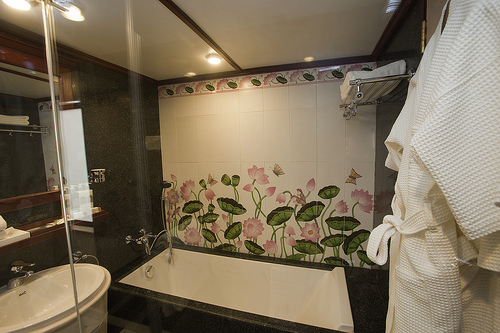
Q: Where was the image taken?
A: It was taken at the bathroom.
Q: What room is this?
A: It is a bathroom.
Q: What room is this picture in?
A: It is at the bathroom.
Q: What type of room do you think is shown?
A: It is a bathroom.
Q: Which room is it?
A: It is a bathroom.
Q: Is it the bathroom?
A: Yes, it is the bathroom.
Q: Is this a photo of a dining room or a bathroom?
A: It is showing a bathroom.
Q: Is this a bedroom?
A: No, it is a bathroom.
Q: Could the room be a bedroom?
A: No, it is a bathroom.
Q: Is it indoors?
A: Yes, it is indoors.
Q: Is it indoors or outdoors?
A: It is indoors.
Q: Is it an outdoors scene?
A: No, it is indoors.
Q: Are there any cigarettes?
A: No, there are no cigarettes.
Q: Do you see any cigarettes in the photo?
A: No, there are no cigarettes.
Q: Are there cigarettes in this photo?
A: No, there are no cigarettes.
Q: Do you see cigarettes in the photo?
A: No, there are no cigarettes.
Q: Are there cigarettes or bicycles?
A: No, there are no cigarettes or bicycles.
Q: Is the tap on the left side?
A: Yes, the tap is on the left of the image.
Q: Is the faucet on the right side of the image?
A: No, the faucet is on the left of the image.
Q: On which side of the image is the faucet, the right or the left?
A: The faucet is on the left of the image.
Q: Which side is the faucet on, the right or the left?
A: The faucet is on the left of the image.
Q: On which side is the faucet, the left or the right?
A: The faucet is on the left of the image.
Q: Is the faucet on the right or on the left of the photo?
A: The faucet is on the left of the image.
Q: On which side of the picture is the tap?
A: The tap is on the left of the image.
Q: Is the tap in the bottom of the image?
A: Yes, the tap is in the bottom of the image.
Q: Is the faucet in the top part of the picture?
A: No, the faucet is in the bottom of the image.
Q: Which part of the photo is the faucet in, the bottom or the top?
A: The faucet is in the bottom of the image.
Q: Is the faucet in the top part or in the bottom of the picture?
A: The faucet is in the bottom of the image.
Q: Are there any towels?
A: Yes, there is a towel.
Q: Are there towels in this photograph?
A: Yes, there is a towel.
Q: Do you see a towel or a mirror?
A: Yes, there is a towel.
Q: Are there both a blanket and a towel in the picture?
A: No, there is a towel but no blankets.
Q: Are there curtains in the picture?
A: No, there are no curtains.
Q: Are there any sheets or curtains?
A: No, there are no curtains or sheets.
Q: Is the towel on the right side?
A: Yes, the towel is on the right of the image.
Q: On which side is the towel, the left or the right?
A: The towel is on the right of the image.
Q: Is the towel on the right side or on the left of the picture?
A: The towel is on the right of the image.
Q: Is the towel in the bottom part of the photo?
A: No, the towel is in the top of the image.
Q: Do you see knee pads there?
A: No, there are no knee pads.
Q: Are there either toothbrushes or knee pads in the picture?
A: No, there are no knee pads or toothbrushes.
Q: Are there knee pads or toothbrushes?
A: No, there are no knee pads or toothbrushes.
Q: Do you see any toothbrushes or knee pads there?
A: No, there are no knee pads or toothbrushes.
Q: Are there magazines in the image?
A: No, there are no magazines.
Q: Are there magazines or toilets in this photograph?
A: No, there are no magazines or toilets.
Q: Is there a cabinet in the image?
A: No, there are no cabinets.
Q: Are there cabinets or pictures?
A: No, there are no cabinets or pictures.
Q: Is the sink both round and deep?
A: Yes, the sink is round and deep.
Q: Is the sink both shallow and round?
A: No, the sink is round but deep.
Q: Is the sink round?
A: Yes, the sink is round.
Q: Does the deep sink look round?
A: Yes, the sink is round.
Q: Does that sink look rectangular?
A: No, the sink is round.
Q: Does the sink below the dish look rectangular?
A: No, the sink is round.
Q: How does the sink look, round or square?
A: The sink is round.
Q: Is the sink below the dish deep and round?
A: Yes, the sink is deep and round.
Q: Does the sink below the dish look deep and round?
A: Yes, the sink is deep and round.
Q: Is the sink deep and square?
A: No, the sink is deep but round.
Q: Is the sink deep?
A: Yes, the sink is deep.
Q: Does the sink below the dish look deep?
A: Yes, the sink is deep.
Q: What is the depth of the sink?
A: The sink is deep.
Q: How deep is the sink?
A: The sink is deep.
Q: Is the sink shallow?
A: No, the sink is deep.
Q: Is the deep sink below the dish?
A: Yes, the sink is below the dish.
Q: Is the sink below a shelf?
A: No, the sink is below the dish.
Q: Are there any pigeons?
A: No, there are no pigeons.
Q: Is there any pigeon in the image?
A: No, there are no pigeons.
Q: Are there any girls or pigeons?
A: No, there are no pigeons or girls.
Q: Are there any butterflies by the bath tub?
A: Yes, there is a butterfly by the bath tub.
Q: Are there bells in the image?
A: No, there are no bells.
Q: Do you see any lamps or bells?
A: No, there are no bells or lamps.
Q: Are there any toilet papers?
A: No, there are no toilet papers.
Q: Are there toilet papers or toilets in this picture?
A: No, there are no toilet papers or toilets.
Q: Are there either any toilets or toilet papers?
A: No, there are no toilet papers or toilets.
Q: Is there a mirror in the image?
A: Yes, there is a mirror.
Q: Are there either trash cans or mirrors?
A: Yes, there is a mirror.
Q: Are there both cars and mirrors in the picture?
A: No, there is a mirror but no cars.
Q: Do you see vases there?
A: No, there are no vases.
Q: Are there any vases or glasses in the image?
A: No, there are no vases or glasses.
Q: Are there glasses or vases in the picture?
A: No, there are no vases or glasses.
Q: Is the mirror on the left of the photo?
A: Yes, the mirror is on the left of the image.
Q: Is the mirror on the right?
A: No, the mirror is on the left of the image.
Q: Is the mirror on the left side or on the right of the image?
A: The mirror is on the left of the image.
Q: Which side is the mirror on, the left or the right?
A: The mirror is on the left of the image.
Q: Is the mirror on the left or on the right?
A: The mirror is on the left of the image.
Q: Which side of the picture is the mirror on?
A: The mirror is on the left of the image.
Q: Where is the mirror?
A: The mirror is in the bathroom.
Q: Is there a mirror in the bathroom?
A: Yes, there is a mirror in the bathroom.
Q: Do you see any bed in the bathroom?
A: No, there is a mirror in the bathroom.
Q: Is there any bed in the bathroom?
A: No, there is a mirror in the bathroom.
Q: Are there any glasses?
A: No, there are no glasses.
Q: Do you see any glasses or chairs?
A: No, there are no glasses or chairs.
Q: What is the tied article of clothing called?
A: The clothing item is a robe.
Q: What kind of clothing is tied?
A: The clothing is a robe.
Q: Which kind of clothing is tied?
A: The clothing is a robe.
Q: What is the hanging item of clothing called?
A: The clothing item is a robe.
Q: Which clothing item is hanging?
A: The clothing item is a robe.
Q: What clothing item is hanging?
A: The clothing item is a robe.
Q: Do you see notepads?
A: No, there are no notepads.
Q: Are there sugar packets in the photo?
A: No, there are no sugar packets.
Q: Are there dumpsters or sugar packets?
A: No, there are no sugar packets or dumpsters.